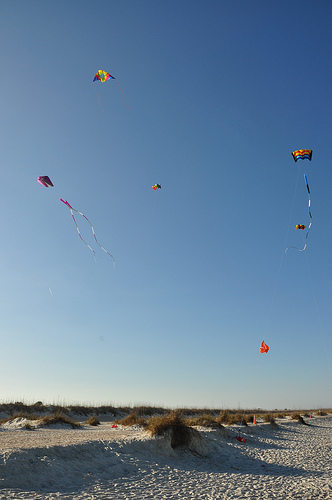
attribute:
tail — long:
[59, 195, 116, 271]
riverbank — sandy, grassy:
[9, 431, 330, 498]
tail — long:
[283, 168, 312, 255]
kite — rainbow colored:
[90, 65, 116, 85]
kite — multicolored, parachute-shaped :
[288, 221, 311, 234]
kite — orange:
[91, 69, 133, 120]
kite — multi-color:
[283, 142, 315, 167]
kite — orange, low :
[258, 339, 269, 354]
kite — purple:
[34, 175, 56, 189]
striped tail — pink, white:
[60, 193, 120, 274]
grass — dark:
[148, 410, 191, 448]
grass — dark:
[116, 413, 146, 426]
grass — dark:
[188, 416, 222, 426]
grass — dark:
[39, 414, 82, 428]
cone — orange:
[243, 389, 268, 425]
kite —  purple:
[35, 172, 117, 266]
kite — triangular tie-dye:
[92, 69, 115, 85]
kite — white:
[151, 182, 160, 190]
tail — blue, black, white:
[278, 172, 314, 262]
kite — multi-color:
[288, 143, 317, 168]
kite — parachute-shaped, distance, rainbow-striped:
[151, 182, 160, 191]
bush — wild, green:
[155, 403, 236, 421]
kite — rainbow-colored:
[88, 66, 125, 122]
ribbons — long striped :
[60, 194, 117, 256]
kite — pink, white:
[36, 175, 118, 275]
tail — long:
[281, 163, 316, 261]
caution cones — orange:
[249, 411, 314, 426]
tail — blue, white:
[288, 167, 316, 255]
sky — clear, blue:
[1, 1, 331, 403]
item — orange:
[251, 414, 260, 430]